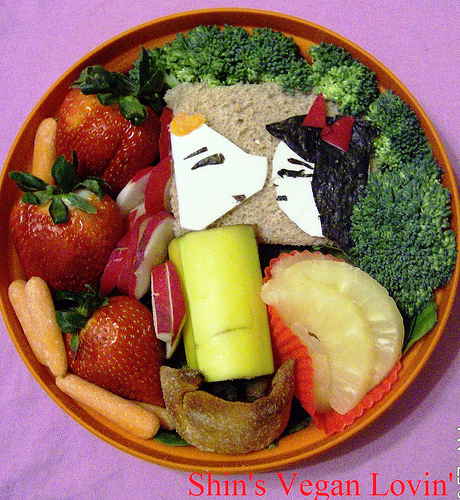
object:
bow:
[2, 5, 460, 480]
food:
[156, 22, 315, 96]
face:
[272, 139, 327, 238]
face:
[172, 118, 268, 232]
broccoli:
[350, 165, 457, 317]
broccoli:
[363, 89, 439, 172]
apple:
[163, 259, 189, 359]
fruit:
[115, 166, 156, 217]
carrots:
[31, 117, 60, 193]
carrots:
[54, 373, 160, 441]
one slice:
[168, 104, 268, 232]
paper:
[168, 114, 267, 232]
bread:
[162, 79, 346, 244]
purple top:
[1, 2, 460, 196]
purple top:
[1, 313, 460, 498]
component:
[178, 224, 274, 382]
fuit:
[158, 366, 295, 456]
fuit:
[284, 259, 406, 396]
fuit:
[54, 46, 168, 192]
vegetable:
[308, 42, 380, 116]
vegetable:
[149, 22, 297, 87]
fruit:
[54, 279, 165, 405]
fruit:
[258, 281, 376, 416]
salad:
[3, 24, 455, 451]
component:
[6, 151, 123, 295]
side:
[1, 5, 241, 472]